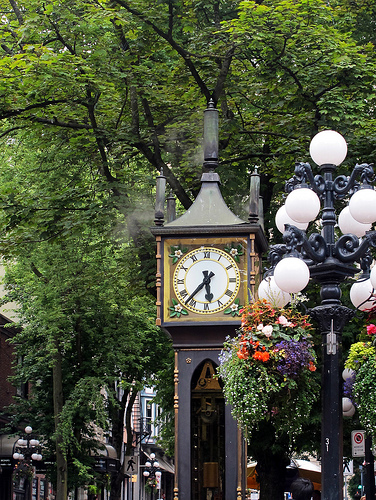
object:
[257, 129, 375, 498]
lamp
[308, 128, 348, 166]
orb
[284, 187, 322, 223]
orb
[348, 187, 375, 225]
orb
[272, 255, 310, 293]
orb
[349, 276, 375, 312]
orb